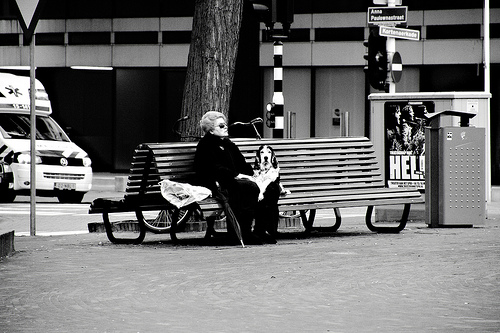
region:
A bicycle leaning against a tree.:
[131, 111, 319, 224]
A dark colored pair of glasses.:
[206, 120, 233, 130]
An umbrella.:
[204, 177, 249, 249]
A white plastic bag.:
[154, 170, 214, 210]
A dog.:
[249, 137, 298, 202]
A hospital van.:
[0, 70, 97, 205]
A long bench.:
[94, 124, 426, 239]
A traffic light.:
[254, 99, 281, 126]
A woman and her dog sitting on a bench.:
[194, 100, 302, 245]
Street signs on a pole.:
[360, 0, 432, 55]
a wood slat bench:
[149, 134, 421, 240]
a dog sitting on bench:
[244, 141, 290, 201]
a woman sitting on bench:
[190, 108, 275, 243]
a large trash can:
[419, 102, 488, 227]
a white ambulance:
[0, 70, 99, 202]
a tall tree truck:
[172, 0, 244, 152]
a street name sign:
[363, 5, 410, 25]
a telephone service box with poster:
[366, 89, 491, 217]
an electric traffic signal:
[263, 100, 273, 125]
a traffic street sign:
[9, 0, 49, 235]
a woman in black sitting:
[189, 108, 265, 262]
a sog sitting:
[251, 141, 299, 208]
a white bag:
[154, 176, 211, 210]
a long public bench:
[146, 144, 420, 226]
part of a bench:
[92, 142, 156, 252]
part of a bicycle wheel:
[132, 209, 190, 233]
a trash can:
[415, 95, 497, 239]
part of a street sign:
[9, 1, 51, 47]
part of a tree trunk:
[165, 2, 238, 148]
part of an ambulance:
[0, 70, 99, 206]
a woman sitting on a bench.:
[174, 110, 283, 252]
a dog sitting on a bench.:
[226, 115, 298, 215]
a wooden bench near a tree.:
[85, 123, 421, 258]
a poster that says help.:
[374, 93, 444, 200]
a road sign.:
[0, 3, 64, 235]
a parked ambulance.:
[0, 64, 102, 203]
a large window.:
[313, 66, 373, 141]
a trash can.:
[416, 107, 491, 235]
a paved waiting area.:
[3, 208, 497, 331]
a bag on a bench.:
[152, 170, 223, 214]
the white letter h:
[383, 151, 410, 187]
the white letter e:
[399, 154, 419, 179]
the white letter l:
[406, 152, 422, 187]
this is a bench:
[90, 109, 428, 248]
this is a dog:
[238, 136, 294, 199]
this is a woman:
[191, 97, 288, 233]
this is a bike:
[131, 112, 308, 231]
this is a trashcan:
[409, 109, 491, 247]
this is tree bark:
[176, 45, 228, 90]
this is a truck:
[0, 57, 107, 209]